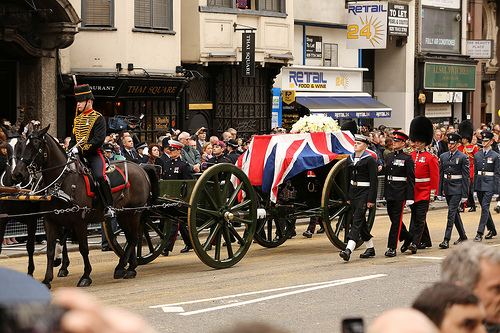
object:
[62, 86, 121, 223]
man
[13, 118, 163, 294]
horse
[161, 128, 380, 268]
wagon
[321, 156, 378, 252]
wheel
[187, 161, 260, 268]
wheel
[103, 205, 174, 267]
wheel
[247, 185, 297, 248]
wheel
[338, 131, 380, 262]
man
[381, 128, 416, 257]
man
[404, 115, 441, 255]
man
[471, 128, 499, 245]
man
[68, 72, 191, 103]
sign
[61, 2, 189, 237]
restaurant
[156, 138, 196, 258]
man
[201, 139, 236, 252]
man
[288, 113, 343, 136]
flowers